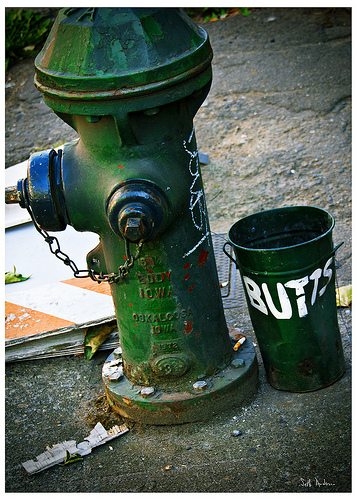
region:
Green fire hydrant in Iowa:
[9, 11, 344, 484]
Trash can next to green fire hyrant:
[225, 182, 351, 411]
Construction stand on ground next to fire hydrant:
[0, 15, 117, 387]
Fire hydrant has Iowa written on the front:
[25, 10, 287, 482]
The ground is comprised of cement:
[29, 268, 347, 499]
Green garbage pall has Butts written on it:
[232, 193, 347, 411]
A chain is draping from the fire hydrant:
[11, 135, 186, 309]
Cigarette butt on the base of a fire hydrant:
[221, 325, 254, 385]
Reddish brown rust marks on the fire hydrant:
[113, 232, 221, 367]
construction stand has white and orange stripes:
[6, 196, 121, 378]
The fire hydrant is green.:
[36, 58, 241, 390]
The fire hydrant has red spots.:
[158, 255, 221, 344]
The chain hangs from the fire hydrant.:
[30, 195, 174, 295]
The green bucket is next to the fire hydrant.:
[228, 214, 354, 391]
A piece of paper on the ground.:
[22, 417, 149, 476]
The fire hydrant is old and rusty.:
[88, 209, 258, 423]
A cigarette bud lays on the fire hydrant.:
[233, 328, 251, 356]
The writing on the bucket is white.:
[237, 273, 339, 322]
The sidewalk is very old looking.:
[22, 357, 301, 490]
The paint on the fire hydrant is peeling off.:
[81, 22, 220, 82]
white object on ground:
[88, 422, 139, 445]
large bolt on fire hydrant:
[138, 385, 158, 400]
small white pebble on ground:
[160, 460, 182, 472]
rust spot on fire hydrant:
[107, 400, 134, 416]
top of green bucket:
[218, 204, 336, 254]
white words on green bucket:
[239, 261, 353, 331]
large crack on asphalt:
[220, 87, 297, 108]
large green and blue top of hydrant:
[47, 11, 211, 92]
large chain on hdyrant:
[21, 178, 155, 290]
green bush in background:
[17, 20, 35, 46]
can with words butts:
[216, 202, 349, 394]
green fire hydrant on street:
[2, 165, 254, 422]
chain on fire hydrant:
[1, 189, 160, 280]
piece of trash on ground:
[11, 413, 125, 475]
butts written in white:
[238, 258, 341, 339]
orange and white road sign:
[0, 295, 108, 349]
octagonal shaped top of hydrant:
[35, 11, 212, 127]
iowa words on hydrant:
[128, 269, 182, 305]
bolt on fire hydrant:
[117, 215, 153, 247]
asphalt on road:
[249, 69, 330, 136]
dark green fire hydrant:
[15, 74, 262, 434]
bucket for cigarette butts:
[217, 204, 349, 390]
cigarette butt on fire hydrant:
[226, 324, 259, 365]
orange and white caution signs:
[8, 221, 129, 356]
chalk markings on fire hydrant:
[172, 119, 227, 268]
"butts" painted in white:
[234, 264, 344, 322]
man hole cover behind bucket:
[210, 227, 270, 309]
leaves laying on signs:
[5, 257, 112, 354]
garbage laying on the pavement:
[21, 422, 144, 465]